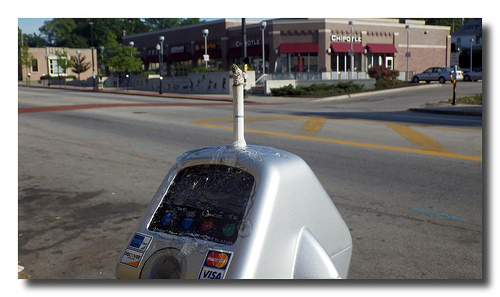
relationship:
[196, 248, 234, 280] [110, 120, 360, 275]
logo on machine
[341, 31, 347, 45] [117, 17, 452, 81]
p on building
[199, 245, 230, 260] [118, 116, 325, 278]
logo on machine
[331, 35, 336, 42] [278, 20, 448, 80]
letter on building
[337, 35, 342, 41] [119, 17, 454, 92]
letter h on building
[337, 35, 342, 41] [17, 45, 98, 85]
letter h on building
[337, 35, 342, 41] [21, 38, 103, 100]
letter h on building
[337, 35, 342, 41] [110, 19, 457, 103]
letter h on building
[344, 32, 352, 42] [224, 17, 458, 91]
o on building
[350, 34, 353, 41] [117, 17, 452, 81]
t on building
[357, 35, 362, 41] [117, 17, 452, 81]
letter on building